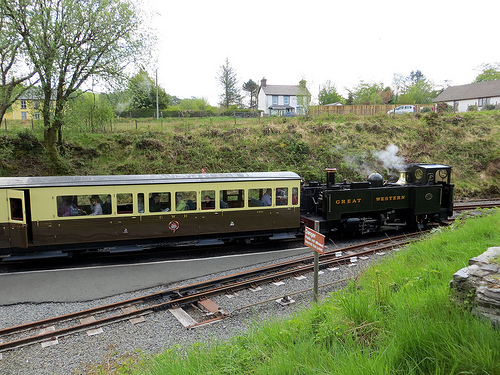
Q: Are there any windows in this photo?
A: Yes, there is a window.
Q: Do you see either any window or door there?
A: Yes, there is a window.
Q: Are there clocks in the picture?
A: No, there are no clocks.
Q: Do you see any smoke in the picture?
A: Yes, there is smoke.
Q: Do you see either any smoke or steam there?
A: Yes, there is smoke.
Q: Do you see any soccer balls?
A: No, there are no soccer balls.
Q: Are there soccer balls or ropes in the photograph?
A: No, there are no soccer balls or ropes.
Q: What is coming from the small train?
A: The smoke is coming from the train.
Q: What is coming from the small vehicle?
A: The smoke is coming from the train.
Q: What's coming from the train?
A: The smoke is coming from the train.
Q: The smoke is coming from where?
A: The smoke is coming from the train.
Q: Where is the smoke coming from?
A: The smoke is coming from the train.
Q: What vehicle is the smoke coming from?
A: The smoke is coming from the train.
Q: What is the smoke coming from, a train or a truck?
A: The smoke is coming from a train.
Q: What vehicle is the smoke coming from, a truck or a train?
A: The smoke is coming from a train.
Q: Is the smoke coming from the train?
A: Yes, the smoke is coming from the train.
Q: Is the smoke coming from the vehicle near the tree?
A: Yes, the smoke is coming from the train.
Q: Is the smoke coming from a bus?
A: No, the smoke is coming from the train.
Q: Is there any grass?
A: Yes, there is grass.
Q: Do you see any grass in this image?
A: Yes, there is grass.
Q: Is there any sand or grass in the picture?
A: Yes, there is grass.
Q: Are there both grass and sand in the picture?
A: No, there is grass but no sand.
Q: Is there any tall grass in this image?
A: Yes, there is tall grass.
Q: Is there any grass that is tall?
A: Yes, there is grass that is tall.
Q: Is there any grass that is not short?
A: Yes, there is tall grass.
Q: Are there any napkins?
A: No, there are no napkins.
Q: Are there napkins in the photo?
A: No, there are no napkins.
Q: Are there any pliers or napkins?
A: No, there are no napkins or pliers.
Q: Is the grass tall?
A: Yes, the grass is tall.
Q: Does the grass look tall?
A: Yes, the grass is tall.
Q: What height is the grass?
A: The grass is tall.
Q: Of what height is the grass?
A: The grass is tall.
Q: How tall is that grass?
A: The grass is tall.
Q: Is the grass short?
A: No, the grass is tall.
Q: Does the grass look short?
A: No, the grass is tall.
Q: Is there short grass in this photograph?
A: No, there is grass but it is tall.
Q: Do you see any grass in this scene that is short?
A: No, there is grass but it is tall.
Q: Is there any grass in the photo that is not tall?
A: No, there is grass but it is tall.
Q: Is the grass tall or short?
A: The grass is tall.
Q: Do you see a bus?
A: No, there are no buses.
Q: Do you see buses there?
A: No, there are no buses.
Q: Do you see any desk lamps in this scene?
A: No, there are no desk lamps.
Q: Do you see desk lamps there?
A: No, there are no desk lamps.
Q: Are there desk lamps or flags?
A: No, there are no desk lamps or flags.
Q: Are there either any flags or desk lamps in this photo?
A: No, there are no desk lamps or flags.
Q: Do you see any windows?
A: Yes, there is a window.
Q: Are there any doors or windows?
A: Yes, there is a window.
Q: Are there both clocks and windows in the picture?
A: No, there is a window but no clocks.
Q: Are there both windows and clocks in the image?
A: No, there is a window but no clocks.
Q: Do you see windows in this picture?
A: Yes, there is a window.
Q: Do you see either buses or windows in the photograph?
A: Yes, there is a window.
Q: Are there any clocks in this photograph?
A: No, there are no clocks.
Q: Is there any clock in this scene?
A: No, there are no clocks.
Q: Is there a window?
A: Yes, there is a window.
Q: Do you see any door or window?
A: Yes, there is a window.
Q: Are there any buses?
A: No, there are no buses.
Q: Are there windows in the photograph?
A: Yes, there is a window.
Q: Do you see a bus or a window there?
A: Yes, there is a window.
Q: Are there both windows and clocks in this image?
A: No, there is a window but no clocks.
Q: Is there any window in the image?
A: Yes, there is a window.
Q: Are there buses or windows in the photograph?
A: Yes, there is a window.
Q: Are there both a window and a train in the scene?
A: Yes, there are both a window and a train.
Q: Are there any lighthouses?
A: No, there are no lighthouses.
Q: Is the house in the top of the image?
A: Yes, the house is in the top of the image.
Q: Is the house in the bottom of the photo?
A: No, the house is in the top of the image.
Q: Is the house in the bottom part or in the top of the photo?
A: The house is in the top of the image.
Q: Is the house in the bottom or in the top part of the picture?
A: The house is in the top of the image.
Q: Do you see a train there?
A: Yes, there is a train.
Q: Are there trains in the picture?
A: Yes, there is a train.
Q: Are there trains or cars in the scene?
A: Yes, there is a train.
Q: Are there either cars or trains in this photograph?
A: Yes, there is a train.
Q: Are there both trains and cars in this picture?
A: Yes, there are both a train and cars.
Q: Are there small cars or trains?
A: Yes, there is a small train.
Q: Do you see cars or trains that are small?
A: Yes, the train is small.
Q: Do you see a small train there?
A: Yes, there is a small train.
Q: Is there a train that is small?
A: Yes, there is a train that is small.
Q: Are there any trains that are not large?
A: Yes, there is a small train.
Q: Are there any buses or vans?
A: No, there are no buses or vans.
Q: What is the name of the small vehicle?
A: The vehicle is a train.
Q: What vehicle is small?
A: The vehicle is a train.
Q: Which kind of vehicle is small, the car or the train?
A: The train is small.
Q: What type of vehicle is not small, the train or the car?
A: The car is not small.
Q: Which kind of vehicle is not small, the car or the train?
A: The car is not small.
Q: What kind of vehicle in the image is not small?
A: The vehicle is a car.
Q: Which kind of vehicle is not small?
A: The vehicle is a car.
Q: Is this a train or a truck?
A: This is a train.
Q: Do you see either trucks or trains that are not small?
A: No, there is a train but it is small.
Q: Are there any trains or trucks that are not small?
A: No, there is a train but it is small.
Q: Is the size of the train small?
A: Yes, the train is small.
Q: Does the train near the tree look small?
A: Yes, the train is small.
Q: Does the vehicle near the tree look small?
A: Yes, the train is small.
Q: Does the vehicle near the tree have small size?
A: Yes, the train is small.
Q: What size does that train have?
A: The train has small size.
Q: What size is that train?
A: The train is small.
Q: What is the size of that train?
A: The train is small.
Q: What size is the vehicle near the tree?
A: The train is small.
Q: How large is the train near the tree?
A: The train is small.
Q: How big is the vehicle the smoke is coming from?
A: The train is small.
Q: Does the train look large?
A: No, the train is small.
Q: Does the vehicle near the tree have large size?
A: No, the train is small.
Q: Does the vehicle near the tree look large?
A: No, the train is small.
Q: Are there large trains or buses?
A: No, there is a train but it is small.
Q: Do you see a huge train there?
A: No, there is a train but it is small.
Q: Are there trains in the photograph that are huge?
A: No, there is a train but it is small.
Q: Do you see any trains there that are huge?
A: No, there is a train but it is small.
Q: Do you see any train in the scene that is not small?
A: No, there is a train but it is small.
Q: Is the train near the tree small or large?
A: The train is small.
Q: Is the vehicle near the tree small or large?
A: The train is small.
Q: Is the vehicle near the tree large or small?
A: The train is small.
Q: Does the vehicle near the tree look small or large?
A: The train is small.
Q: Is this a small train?
A: Yes, this is a small train.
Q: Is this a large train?
A: No, this is a small train.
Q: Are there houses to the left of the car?
A: Yes, there is a house to the left of the car.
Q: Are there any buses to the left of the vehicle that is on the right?
A: No, there is a house to the left of the car.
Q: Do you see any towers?
A: No, there are no towers.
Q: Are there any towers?
A: No, there are no towers.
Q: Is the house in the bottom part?
A: No, the house is in the top of the image.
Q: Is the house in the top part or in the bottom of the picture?
A: The house is in the top of the image.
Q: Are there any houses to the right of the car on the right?
A: Yes, there is a house to the right of the car.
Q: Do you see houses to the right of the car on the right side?
A: Yes, there is a house to the right of the car.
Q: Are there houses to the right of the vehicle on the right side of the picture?
A: Yes, there is a house to the right of the car.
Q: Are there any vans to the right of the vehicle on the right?
A: No, there is a house to the right of the car.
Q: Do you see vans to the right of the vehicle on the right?
A: No, there is a house to the right of the car.